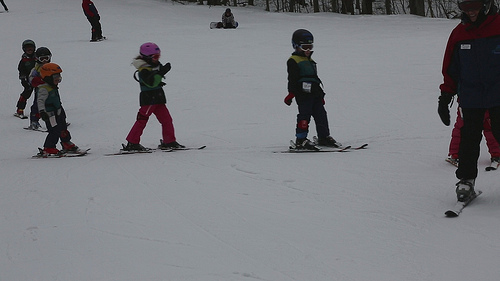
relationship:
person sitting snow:
[221, 7, 236, 28] [0, 0, 499, 280]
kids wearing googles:
[36, 30, 491, 237] [287, 30, 338, 48]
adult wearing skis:
[426, 0, 499, 180] [442, 188, 482, 217]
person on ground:
[221, 8, 236, 28] [0, 1, 498, 279]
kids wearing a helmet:
[284, 28, 343, 149] [278, 21, 317, 54]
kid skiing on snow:
[126, 42, 186, 151] [13, 28, 405, 179]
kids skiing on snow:
[284, 29, 349, 149] [13, 28, 405, 179]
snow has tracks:
[0, 0, 499, 280] [227, 161, 306, 194]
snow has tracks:
[0, 0, 499, 280] [356, 132, 454, 143]